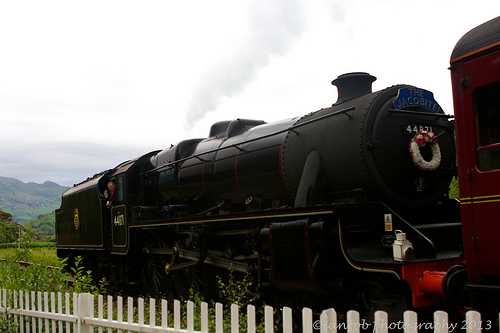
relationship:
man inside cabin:
[98, 177, 128, 214] [46, 144, 147, 269]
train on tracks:
[53, 13, 500, 319] [9, 254, 87, 293]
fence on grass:
[1, 289, 482, 331] [2, 248, 279, 331]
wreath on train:
[401, 126, 448, 174] [48, 65, 450, 321]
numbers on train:
[404, 114, 439, 139] [41, 10, 485, 305]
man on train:
[105, 181, 118, 208] [48, 63, 460, 297]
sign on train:
[71, 205, 82, 230] [57, 11, 498, 324]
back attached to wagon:
[50, 164, 114, 275] [96, 104, 494, 262]